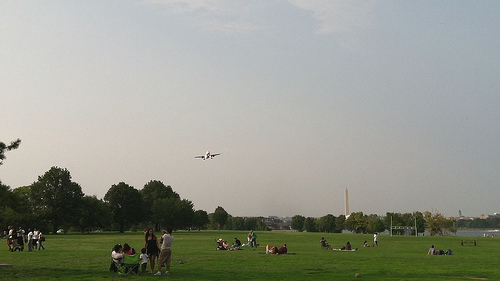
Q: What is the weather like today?
A: It is cloudy.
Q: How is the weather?
A: It is cloudy.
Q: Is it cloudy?
A: Yes, it is cloudy.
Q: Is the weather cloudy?
A: Yes, it is cloudy.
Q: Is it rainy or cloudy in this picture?
A: It is cloudy.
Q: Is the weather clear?
A: No, it is cloudy.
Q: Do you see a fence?
A: No, there are no fences.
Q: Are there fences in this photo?
A: No, there are no fences.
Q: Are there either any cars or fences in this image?
A: No, there are no fences or cars.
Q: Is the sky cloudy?
A: Yes, the sky is cloudy.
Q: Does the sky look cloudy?
A: Yes, the sky is cloudy.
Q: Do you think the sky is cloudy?
A: Yes, the sky is cloudy.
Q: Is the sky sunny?
A: No, the sky is cloudy.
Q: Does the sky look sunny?
A: No, the sky is cloudy.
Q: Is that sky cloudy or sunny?
A: The sky is cloudy.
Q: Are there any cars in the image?
A: No, there are no cars.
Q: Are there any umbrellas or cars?
A: No, there are no cars or umbrellas.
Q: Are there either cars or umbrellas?
A: No, there are no cars or umbrellas.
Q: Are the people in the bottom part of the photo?
A: Yes, the people are in the bottom of the image.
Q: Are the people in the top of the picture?
A: No, the people are in the bottom of the image.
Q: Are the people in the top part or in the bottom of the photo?
A: The people are in the bottom of the image.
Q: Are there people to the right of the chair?
A: Yes, there are people to the right of the chair.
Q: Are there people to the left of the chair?
A: No, the people are to the right of the chair.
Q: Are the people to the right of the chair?
A: Yes, the people are to the right of the chair.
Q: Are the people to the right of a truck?
A: No, the people are to the right of the chair.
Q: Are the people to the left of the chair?
A: No, the people are to the right of the chair.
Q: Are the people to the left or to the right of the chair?
A: The people are to the right of the chair.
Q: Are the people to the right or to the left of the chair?
A: The people are to the right of the chair.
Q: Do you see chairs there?
A: Yes, there is a chair.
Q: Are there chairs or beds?
A: Yes, there is a chair.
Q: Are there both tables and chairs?
A: No, there is a chair but no tables.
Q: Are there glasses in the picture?
A: No, there are no glasses.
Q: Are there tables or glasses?
A: No, there are no glasses or tables.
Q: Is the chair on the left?
A: Yes, the chair is on the left of the image.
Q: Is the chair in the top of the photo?
A: No, the chair is in the bottom of the image.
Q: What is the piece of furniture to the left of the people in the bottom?
A: The piece of furniture is a chair.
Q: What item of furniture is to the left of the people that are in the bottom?
A: The piece of furniture is a chair.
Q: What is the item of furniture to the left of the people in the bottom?
A: The piece of furniture is a chair.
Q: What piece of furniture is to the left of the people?
A: The piece of furniture is a chair.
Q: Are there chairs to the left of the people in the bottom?
A: Yes, there is a chair to the left of the people.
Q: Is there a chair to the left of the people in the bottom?
A: Yes, there is a chair to the left of the people.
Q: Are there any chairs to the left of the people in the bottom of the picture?
A: Yes, there is a chair to the left of the people.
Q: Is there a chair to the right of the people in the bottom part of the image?
A: No, the chair is to the left of the people.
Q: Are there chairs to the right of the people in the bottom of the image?
A: No, the chair is to the left of the people.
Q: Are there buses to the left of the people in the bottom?
A: No, there is a chair to the left of the people.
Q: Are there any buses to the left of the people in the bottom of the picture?
A: No, there is a chair to the left of the people.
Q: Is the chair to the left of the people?
A: Yes, the chair is to the left of the people.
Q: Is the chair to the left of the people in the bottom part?
A: Yes, the chair is to the left of the people.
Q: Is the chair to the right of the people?
A: No, the chair is to the left of the people.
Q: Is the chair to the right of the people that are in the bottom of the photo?
A: No, the chair is to the left of the people.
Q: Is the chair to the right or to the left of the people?
A: The chair is to the left of the people.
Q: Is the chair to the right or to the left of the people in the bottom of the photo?
A: The chair is to the left of the people.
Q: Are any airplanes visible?
A: Yes, there is an airplane.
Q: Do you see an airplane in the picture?
A: Yes, there is an airplane.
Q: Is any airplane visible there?
A: Yes, there is an airplane.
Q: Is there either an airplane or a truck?
A: Yes, there is an airplane.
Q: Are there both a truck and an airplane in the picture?
A: No, there is an airplane but no trucks.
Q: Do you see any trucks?
A: No, there are no trucks.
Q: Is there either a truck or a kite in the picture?
A: No, there are no trucks or kites.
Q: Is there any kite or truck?
A: No, there are no trucks or kites.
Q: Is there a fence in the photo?
A: No, there are no fences.